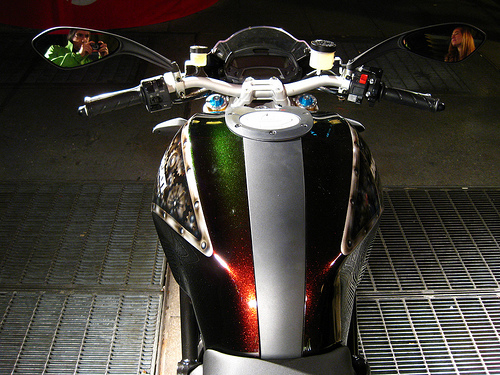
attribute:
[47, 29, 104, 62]
man — brunette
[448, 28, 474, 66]
woman — brunette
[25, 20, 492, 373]
motorcycle — colored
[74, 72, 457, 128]
handlebars — soft, black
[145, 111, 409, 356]
tank — fancy, striped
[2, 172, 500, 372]
grill — rusty, dirty, gray, metallic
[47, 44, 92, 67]
jacket — green